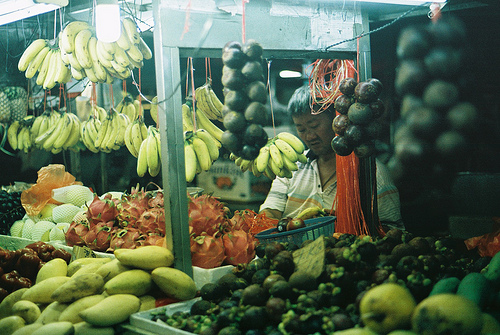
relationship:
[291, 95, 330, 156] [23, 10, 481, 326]
man at fruit stand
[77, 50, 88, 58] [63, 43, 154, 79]
banana in bunch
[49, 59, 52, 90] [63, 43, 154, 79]
banana in bunch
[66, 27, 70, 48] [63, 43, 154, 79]
banana in bunch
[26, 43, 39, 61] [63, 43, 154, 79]
banana in bunch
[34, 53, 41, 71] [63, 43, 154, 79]
banana in bunch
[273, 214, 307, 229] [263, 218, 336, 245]
fruit in bowl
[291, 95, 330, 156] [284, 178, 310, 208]
man wearing shirt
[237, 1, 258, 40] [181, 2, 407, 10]
cord on ceiling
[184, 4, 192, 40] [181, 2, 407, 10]
cord on ceiling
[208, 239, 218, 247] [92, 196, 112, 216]
spike on fruit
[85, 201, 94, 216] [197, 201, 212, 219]
spike on fruit